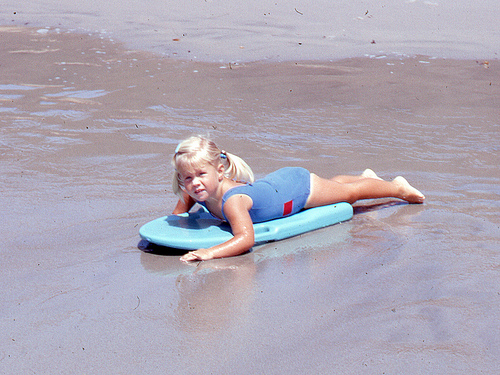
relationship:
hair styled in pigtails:
[170, 134, 254, 198] [171, 170, 184, 200]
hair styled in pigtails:
[170, 134, 254, 198] [212, 150, 254, 184]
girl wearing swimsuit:
[150, 136, 441, 266] [204, 165, 314, 228]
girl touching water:
[150, 136, 441, 266] [1, 1, 499, 374]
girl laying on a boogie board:
[150, 136, 441, 266] [134, 197, 365, 256]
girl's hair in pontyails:
[170, 134, 254, 198] [218, 146, 258, 186]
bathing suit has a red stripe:
[204, 165, 314, 228] [280, 200, 296, 216]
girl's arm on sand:
[179, 206, 263, 269] [1, 27, 499, 375]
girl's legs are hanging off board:
[304, 165, 428, 212] [134, 197, 365, 256]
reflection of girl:
[169, 200, 431, 332] [150, 136, 441, 266]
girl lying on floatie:
[150, 136, 441, 266] [134, 197, 365, 256]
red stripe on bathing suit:
[280, 200, 296, 216] [204, 165, 314, 228]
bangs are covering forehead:
[175, 153, 210, 175] [176, 154, 211, 176]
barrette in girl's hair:
[218, 151, 229, 160] [170, 134, 254, 198]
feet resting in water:
[384, 176, 427, 204] [1, 1, 499, 374]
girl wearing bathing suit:
[150, 136, 441, 266] [204, 165, 314, 228]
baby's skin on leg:
[164, 134, 427, 262] [304, 165, 428, 212]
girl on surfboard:
[150, 136, 441, 266] [134, 197, 365, 256]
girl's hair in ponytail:
[170, 134, 254, 198] [218, 146, 258, 186]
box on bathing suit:
[280, 200, 296, 216] [204, 165, 314, 228]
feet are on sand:
[361, 164, 432, 208] [1, 27, 499, 375]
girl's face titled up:
[164, 132, 264, 214] [167, 136, 257, 203]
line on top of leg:
[303, 171, 317, 209] [304, 165, 428, 212]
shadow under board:
[135, 240, 186, 258] [134, 197, 365, 256]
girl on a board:
[150, 136, 441, 266] [134, 197, 365, 256]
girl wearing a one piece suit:
[150, 136, 441, 266] [204, 165, 314, 228]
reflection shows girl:
[169, 200, 431, 332] [150, 136, 441, 266]